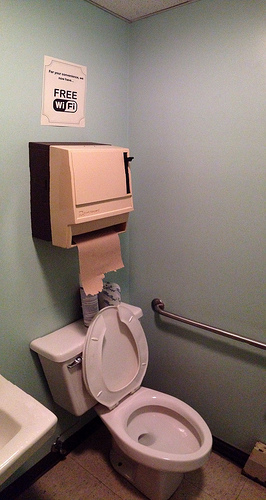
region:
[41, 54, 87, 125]
sign reading "free wifi"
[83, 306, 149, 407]
toilet seat lid in upward position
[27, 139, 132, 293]
napkin dispenser above toilet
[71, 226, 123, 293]
brown paper towels hanging from dispenser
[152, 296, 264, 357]
handicap silver bar attached to wall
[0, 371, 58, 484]
corner edge of sink for washing hands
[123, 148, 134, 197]
black lever to pull down to activate napkins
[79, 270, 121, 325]
unused roll of toilet paper new in wrapper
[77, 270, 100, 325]
bottle of cleaner on back of toilet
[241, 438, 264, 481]
brown box on floor of bathroom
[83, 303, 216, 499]
a toilet in the bathroom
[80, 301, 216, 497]
the lid of toilet is open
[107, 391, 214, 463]
the toilet is clean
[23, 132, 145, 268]
a paper dispenser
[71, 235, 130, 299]
brown paper to dry hands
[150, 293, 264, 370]
a handle on a wall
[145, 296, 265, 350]
handle is color silver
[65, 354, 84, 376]
a handle of tank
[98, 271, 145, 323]
a roll of toilet paper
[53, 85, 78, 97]
The word FREE on the sign above the toilet.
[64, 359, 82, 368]
The flush handle on the toilet.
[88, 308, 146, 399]
The lid and seat of the toilet.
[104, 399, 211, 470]
The bowl of the toilet.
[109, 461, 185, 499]
The base of the toilet.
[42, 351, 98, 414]
The water tank of the toilet.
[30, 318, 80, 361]
The lid of the water tank of the toilet.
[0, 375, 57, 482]
The basin of the sink.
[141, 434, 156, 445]
The drain hole inside of the toilet.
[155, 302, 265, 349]
The silver bar on the wall.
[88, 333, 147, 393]
The toilet seat is up.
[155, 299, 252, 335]
hand railing on the wall.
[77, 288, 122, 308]
Roll of toilet paper on the toilet water bowl.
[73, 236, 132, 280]
Paper towels in the bathroom.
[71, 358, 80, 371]
Handle to flush the toilet.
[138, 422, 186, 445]
Water in the toilet.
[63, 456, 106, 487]
The floor is tiled.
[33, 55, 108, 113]
A white sign on the wall.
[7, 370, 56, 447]
Sink next to the toilet.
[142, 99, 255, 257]
The wall is green.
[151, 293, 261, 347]
silver metal bar on the wall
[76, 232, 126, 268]
brown paper towel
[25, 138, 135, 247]
paper towel dispenser on the bathroom wall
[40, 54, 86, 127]
sign on the wall for free wi-fi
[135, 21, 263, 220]
blue-green bathroom wall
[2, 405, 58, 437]
corner of a white bathroom sink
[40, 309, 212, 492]
white toilet with the seat and lid up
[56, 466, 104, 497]
tiled bathroom floor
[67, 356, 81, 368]
silver handle for flushing the toilet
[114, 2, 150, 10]
white bathroom ceiling